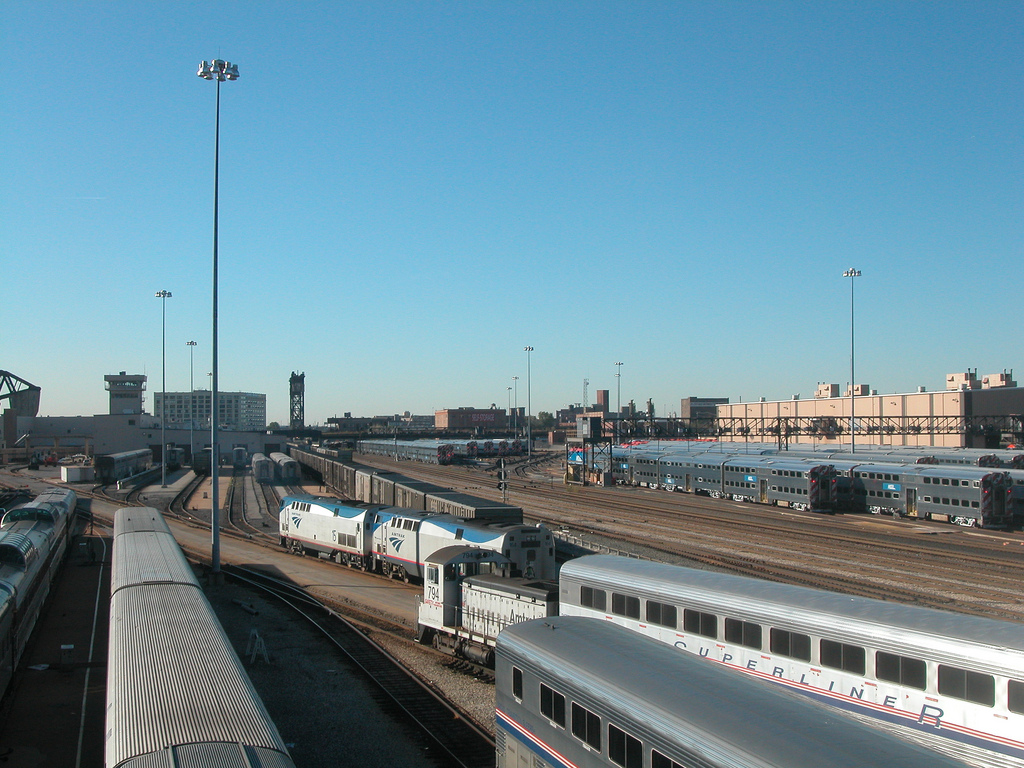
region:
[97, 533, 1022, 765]
the trains are gray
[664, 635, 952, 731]
the train says superliner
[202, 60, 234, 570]
the pole is tall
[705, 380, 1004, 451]
the building is beige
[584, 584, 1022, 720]
the train has many windows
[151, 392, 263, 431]
the building has many windows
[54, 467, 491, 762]
the tracks are brown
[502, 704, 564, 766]
the train has a stripe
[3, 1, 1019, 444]
sky is very clear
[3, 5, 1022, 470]
sky is mostly blue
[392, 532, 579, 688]
small engine on train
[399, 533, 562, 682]
small engine is silver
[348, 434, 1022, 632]
large patch of mud between trains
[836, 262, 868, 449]
tall light pole by building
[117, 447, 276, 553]
set of empty tracks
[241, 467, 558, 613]
train is blue and silver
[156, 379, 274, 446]
multi storied building in distance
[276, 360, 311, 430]
tower in the distance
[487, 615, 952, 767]
a silver passenger train car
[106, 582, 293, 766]
a silver passenger train car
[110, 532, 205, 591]
a silver passenger train car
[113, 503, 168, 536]
a silver passenger train car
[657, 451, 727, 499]
a silver passenger train car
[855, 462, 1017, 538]
a silver passenger train car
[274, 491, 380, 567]
a white and blue train engine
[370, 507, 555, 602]
a white and blue train engine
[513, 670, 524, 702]
gray train has a window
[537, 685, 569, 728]
gray train has a window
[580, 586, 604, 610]
gray train has a window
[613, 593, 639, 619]
gray train has a window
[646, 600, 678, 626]
gray train has a window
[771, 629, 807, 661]
gray train has a window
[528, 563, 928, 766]
the trains are silver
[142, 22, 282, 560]
tall light poles above trains to left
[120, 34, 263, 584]
tall light poles above trains to left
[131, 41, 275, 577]
tall light poles above trains to left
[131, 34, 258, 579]
tall light poles above trains to left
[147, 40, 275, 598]
tall light poles above trains to left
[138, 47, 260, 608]
tall light poles above trains to left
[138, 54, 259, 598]
tall light poles above trains to left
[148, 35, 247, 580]
tall light poles above trains to left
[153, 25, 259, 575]
tall light poles above trains to left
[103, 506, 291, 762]
train is on the track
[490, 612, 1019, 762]
train is on the track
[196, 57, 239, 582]
light fixture is above train tracks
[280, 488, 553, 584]
train is on the track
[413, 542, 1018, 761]
train is on the track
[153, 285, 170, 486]
light fixture is above building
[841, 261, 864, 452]
light fixture is to the right of train depot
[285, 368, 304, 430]
tower is behind train depot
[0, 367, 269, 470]
building is behind train depot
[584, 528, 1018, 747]
gray train car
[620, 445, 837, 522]
gray colored passenger train car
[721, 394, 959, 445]
large brown colored building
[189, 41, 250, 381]
silver colored light post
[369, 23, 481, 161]
blue sky with no clouds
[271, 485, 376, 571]
A train car on a track.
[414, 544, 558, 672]
A train car on a track.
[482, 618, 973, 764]
A train car on a track.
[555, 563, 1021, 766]
A train car on a track.